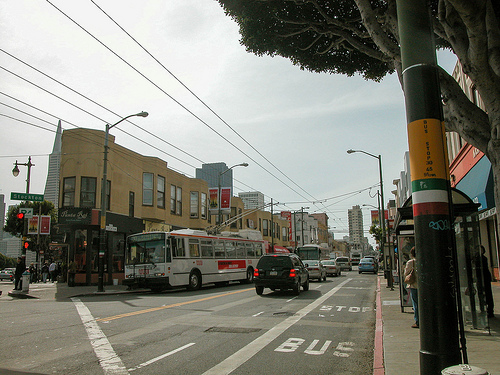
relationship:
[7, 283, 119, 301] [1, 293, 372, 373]
corner of street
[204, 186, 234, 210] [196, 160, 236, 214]
banners on building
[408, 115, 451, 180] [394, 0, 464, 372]
patch on pole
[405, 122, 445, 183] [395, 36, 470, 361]
square patch on pole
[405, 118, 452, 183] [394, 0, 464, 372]
square patch on pole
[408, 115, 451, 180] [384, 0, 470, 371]
patch on pole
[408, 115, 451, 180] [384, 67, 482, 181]
patch on pole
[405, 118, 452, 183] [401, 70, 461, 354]
square patch on pole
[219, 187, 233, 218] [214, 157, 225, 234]
patch on pole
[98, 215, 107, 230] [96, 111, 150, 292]
yellow patch on pole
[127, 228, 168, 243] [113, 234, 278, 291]
marquee display on bus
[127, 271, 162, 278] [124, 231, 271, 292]
headlights on bus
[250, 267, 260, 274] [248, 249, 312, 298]
light on suv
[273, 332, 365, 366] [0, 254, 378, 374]
word bus on street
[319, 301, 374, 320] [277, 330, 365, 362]
stop over word bus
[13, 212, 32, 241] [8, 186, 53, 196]
traffic light under street sign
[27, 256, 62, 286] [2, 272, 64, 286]
people on sidewalk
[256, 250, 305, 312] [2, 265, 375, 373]
suv on road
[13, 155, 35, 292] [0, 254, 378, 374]
light on street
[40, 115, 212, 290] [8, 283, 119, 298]
building on corner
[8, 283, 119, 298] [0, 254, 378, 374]
corner on street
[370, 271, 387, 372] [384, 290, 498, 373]
curb on sidewalk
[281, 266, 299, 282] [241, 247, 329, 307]
brake light on suv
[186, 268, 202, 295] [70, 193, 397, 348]
wheel on bus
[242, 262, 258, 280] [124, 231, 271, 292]
wheel on bus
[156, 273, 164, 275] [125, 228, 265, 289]
headlight on bus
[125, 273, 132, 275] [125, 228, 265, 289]
headlight on bus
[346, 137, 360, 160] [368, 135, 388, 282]
streetlight on pole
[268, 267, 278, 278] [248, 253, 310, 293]
license plate on vehicle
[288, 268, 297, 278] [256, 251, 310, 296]
brake light on suv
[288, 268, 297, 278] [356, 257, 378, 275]
brake light on vehicle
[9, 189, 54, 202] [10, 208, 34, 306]
sign on pole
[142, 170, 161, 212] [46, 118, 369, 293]
windows on building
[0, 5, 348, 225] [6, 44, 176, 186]
wires carrying power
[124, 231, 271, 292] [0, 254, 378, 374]
bus on street